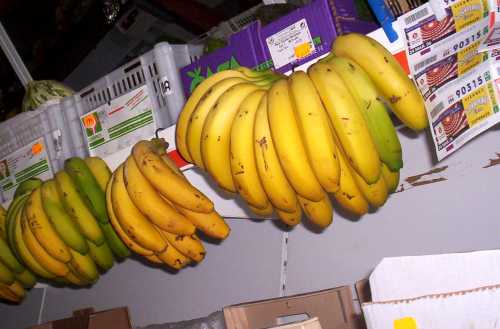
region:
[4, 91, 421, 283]
several bunches of bananas hanging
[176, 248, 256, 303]
white walls of the shop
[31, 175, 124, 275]
green and yellow bananas in a bunch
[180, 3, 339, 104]
a purple cardboard os on a shelf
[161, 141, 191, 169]
an orange stripe on a shelf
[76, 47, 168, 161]
a white plastic bin on a shelf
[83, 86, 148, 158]
green and white label on a bin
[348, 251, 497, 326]
white cardboard box with a yellow sticker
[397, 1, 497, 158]
coupons stuck to the shelf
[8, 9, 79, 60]
brown ceiling of the shop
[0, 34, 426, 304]
the bunches of bananas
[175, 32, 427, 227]
the large bunch of bananas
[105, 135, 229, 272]
the bunch of bananas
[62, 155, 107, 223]
the green banana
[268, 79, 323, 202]
the yellow banana in the bunch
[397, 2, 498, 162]
the paper next to the banana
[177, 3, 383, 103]
the purple box above the bananas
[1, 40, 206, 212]
the white containers above the bananas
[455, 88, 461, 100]
the 9 on the piece of paper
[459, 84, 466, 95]
the 0 on the piece of paper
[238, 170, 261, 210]
part of a banana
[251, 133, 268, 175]
part of a banana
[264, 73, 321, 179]
this is a banana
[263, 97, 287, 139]
the banana is yellow in color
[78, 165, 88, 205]
the banana is green in color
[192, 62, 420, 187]
this is a bunch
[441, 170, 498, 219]
this is a wall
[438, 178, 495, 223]
the wall is white in color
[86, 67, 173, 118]
this is a crate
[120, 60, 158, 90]
the crate is white in color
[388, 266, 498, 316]
this is a box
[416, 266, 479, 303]
the box is white in color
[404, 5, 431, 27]
bar code on paper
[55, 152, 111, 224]
Green banana in bunch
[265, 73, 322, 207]
Yellow banana in bunch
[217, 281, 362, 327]
Box below the bananas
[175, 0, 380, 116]
Purple box above bananas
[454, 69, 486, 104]
Number on the paper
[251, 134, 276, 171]
bruise on yellow banana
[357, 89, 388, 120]
Bruises on green banana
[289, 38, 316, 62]
Yellow sticker on box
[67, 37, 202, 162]
White crate next to purple box